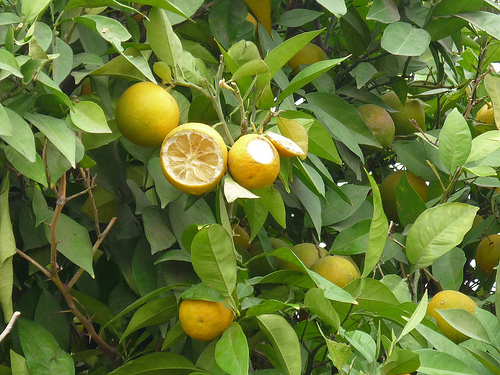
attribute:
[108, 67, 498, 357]
lemons — many, waiting to be picked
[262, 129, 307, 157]
peel — white, inside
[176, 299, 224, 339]
lemon — yellow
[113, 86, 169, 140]
lemon — yellow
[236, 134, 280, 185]
lemon — yellow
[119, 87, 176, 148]
lemon — green, ripe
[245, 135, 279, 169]
part — white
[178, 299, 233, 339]
lemon — ready to be picked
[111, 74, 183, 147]
fruit — citrus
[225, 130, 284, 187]
fruit — citrus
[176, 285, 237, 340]
fruit — citrus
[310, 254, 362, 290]
fruit — citrus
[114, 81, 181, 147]
lemon — yellow, green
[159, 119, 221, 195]
lemon — cut open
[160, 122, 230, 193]
lemon — looks like it was cut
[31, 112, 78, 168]
leaves — bright, green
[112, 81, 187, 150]
lemon — not ripe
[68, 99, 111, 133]
leaf — green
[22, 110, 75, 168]
leaf — green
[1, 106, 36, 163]
leaf — green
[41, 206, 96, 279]
leaf — green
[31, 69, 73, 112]
leaf — green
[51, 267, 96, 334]
twig — thorns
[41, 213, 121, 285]
twig branch — brown, skinny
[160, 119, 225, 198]
lemon — pulp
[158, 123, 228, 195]
fruit — citrus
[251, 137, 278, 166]
rind — white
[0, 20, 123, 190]
leaves — bitten by bugs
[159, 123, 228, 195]
citrus fruit — partially eaten